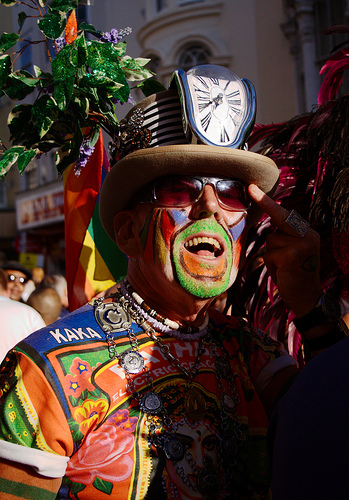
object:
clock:
[168, 64, 257, 152]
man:
[0, 89, 349, 500]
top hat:
[98, 66, 280, 247]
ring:
[281, 209, 310, 238]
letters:
[49, 327, 103, 344]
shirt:
[0, 282, 294, 500]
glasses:
[134, 175, 251, 210]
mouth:
[182, 232, 226, 261]